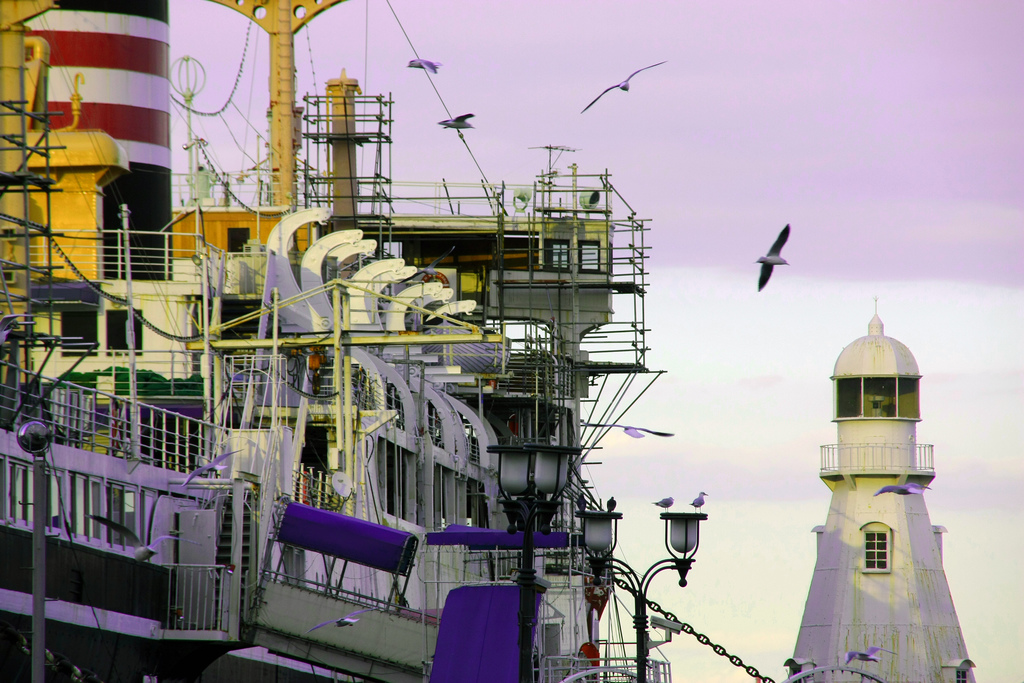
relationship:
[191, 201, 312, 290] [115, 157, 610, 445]
window on building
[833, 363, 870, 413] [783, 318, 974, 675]
window on building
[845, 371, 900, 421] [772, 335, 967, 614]
window on building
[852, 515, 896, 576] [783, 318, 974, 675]
window on building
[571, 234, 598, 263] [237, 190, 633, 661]
windows on boat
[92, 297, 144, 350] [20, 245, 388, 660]
window on boat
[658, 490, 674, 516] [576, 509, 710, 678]
seagull on streetlight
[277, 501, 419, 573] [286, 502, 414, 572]
cover with cover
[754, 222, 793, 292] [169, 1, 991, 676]
bird flying in air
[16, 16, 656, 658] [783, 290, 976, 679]
ship docked near lighthouse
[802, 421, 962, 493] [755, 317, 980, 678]
railing on lighthouse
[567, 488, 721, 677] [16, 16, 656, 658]
pole near ship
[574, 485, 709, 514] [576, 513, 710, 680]
birds sitting on a light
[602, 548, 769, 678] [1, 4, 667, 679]
chain to a boat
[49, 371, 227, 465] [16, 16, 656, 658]
railing on a ship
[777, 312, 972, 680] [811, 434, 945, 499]
lighthouse with walkway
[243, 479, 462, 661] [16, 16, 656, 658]
walkway onto a ship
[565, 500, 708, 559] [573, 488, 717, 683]
lights on lamp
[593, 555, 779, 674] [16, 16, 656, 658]
chain connecting ship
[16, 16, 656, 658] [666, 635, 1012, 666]
ship to dock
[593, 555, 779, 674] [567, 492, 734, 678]
chain behind lampost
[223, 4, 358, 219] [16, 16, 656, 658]
tower rising from ship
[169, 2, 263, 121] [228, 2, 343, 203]
chain attached to tower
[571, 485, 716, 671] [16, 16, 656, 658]
lamp in front of ship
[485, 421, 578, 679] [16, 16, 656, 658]
lamp in front of ship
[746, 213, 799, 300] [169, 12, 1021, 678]
bird flying in sky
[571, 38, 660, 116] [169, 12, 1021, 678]
bird flying in sky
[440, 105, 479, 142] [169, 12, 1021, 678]
bird flying in sky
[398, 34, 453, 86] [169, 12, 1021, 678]
bird flying in sky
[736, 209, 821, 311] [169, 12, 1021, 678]
bird flying in sky